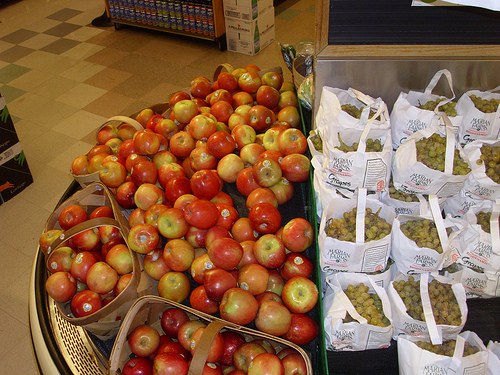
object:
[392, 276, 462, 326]
grapes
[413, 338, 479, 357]
grapes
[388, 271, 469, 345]
bag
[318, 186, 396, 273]
bag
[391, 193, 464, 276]
bag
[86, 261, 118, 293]
apple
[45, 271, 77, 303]
apple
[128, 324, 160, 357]
apple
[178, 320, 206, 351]
apple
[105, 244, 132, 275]
apple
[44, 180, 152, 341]
basket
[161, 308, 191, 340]
apple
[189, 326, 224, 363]
apple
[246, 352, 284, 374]
apple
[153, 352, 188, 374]
apple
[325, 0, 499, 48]
display board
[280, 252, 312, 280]
apples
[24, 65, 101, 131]
ground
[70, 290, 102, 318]
apple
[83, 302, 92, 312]
produce sticker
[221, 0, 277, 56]
boxes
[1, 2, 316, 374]
floor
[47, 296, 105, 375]
grate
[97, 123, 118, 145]
apples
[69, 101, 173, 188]
basket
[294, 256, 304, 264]
sticker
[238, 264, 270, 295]
apple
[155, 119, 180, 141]
apples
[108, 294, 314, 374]
basket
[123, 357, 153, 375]
apples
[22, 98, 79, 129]
tile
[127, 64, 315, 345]
produce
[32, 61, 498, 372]
display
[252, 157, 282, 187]
fruit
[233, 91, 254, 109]
fruit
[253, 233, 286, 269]
fruit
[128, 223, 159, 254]
fruit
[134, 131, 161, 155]
fruit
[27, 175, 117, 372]
table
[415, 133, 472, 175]
grapes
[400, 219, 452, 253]
grapes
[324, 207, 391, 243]
grapes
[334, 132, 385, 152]
grapes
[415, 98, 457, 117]
grapes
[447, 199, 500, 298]
bag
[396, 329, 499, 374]
bag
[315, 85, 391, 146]
bag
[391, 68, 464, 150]
bag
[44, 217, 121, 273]
handle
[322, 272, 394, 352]
bag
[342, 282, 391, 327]
grapes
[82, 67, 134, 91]
tile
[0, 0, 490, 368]
store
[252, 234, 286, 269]
apple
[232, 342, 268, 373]
apple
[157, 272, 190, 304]
apple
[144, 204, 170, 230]
apple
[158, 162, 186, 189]
apple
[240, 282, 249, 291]
sticker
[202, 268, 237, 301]
apple